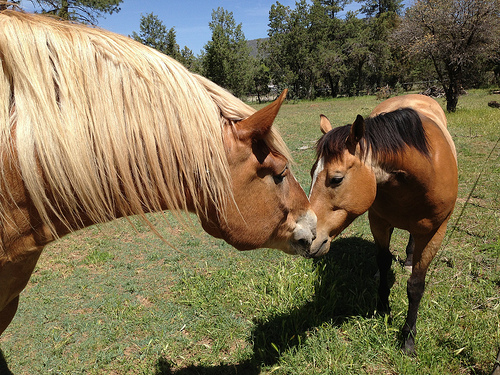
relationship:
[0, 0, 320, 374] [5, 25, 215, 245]
horse has hair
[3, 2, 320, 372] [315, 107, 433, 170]
horse has hair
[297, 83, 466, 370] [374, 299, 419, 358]
horse has hooves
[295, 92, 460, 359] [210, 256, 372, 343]
horse on grass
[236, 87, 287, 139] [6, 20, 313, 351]
ear on horse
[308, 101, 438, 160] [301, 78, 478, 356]
hair on horse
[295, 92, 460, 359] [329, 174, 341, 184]
horse has eye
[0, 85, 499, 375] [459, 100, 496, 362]
grass in field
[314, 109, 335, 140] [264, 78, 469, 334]
ear of horse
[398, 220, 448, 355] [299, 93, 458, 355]
leg of horse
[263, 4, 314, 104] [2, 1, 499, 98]
tree has leaves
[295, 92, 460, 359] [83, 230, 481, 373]
horse standing in grass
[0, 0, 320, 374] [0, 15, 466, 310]
horse touching two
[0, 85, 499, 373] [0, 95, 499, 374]
grass on ground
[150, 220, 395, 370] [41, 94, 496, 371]
shadow on ground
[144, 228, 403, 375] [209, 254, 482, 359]
shadow on ground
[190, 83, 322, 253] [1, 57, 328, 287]
head of horse